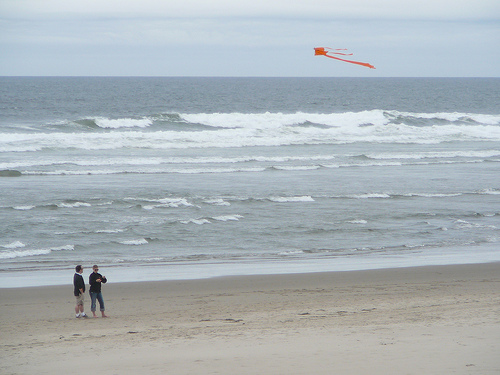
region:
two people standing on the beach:
[39, 234, 168, 372]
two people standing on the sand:
[32, 246, 179, 374]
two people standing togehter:
[36, 232, 167, 362]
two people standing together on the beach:
[43, 234, 178, 367]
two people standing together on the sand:
[48, 236, 243, 368]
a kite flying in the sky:
[211, 25, 423, 125]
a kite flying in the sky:
[298, 36, 370, 86]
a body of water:
[26, 54, 465, 286]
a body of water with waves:
[27, 58, 498, 250]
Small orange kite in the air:
[304, 36, 386, 84]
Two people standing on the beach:
[60, 259, 118, 329]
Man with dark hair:
[64, 261, 94, 321]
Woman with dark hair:
[89, 257, 114, 318]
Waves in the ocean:
[7, 103, 499, 270]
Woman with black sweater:
[84, 256, 114, 321]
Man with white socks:
[66, 253, 96, 323]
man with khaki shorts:
[57, 261, 93, 327]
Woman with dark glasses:
[83, 259, 121, 323]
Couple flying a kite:
[62, 258, 118, 330]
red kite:
[307, 41, 375, 79]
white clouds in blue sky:
[19, 24, 43, 49]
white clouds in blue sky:
[99, 25, 143, 55]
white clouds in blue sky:
[150, 25, 185, 55]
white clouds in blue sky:
[221, 22, 266, 59]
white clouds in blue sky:
[401, 18, 412, 56]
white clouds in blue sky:
[419, 25, 480, 69]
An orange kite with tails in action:
[311, 42, 378, 74]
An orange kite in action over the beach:
[307, 36, 382, 304]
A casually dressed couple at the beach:
[65, 261, 113, 321]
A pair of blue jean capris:
[87, 291, 107, 315]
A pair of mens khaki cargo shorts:
[71, 289, 88, 306]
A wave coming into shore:
[81, 96, 499, 143]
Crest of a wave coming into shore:
[78, 103, 486, 131]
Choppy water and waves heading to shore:
[126, 180, 446, 285]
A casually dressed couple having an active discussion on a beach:
[62, 260, 114, 321]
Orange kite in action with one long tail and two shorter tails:
[309, 41, 392, 77]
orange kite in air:
[290, 46, 378, 88]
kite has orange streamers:
[329, 44, 369, 73]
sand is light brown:
[257, 289, 459, 372]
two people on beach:
[61, 234, 127, 321]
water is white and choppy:
[72, 91, 428, 262]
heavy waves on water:
[49, 127, 441, 219]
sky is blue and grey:
[352, 4, 444, 59]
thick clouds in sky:
[138, 4, 459, 34]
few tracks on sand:
[133, 301, 341, 346]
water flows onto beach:
[0, 244, 482, 326]